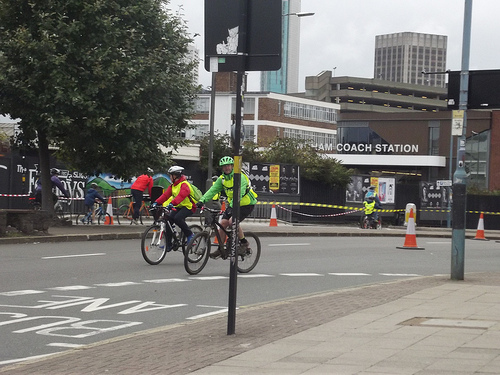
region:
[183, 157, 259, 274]
a man in a green jacket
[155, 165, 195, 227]
a person in a red jacket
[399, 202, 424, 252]
an orange cone in the street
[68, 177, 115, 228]
a little boy on a bike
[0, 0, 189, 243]
a tree in grass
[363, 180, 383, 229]
father and son riding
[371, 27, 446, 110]
a tall office building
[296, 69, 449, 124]
a very large parking garage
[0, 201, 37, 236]
a bench in the park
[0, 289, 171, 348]
white bus lane lettering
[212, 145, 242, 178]
head of a person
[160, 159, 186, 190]
head of a person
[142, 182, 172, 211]
arm of a person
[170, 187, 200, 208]
arm of a person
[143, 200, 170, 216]
hand of a person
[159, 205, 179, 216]
hand of a person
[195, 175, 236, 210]
arm of a person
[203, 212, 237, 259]
leg of a person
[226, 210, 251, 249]
leg of a person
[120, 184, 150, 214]
leg of a person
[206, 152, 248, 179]
head of a person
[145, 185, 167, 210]
arm of a person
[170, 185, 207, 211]
arm of a person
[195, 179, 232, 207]
arm of a person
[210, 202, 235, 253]
leg of a person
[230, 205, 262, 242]
leg of a person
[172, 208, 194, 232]
leg of a person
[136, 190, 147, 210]
leg of a person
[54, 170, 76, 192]
arm of a person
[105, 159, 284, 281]
bikers on the road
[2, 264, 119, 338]
white paint on street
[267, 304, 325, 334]
bricks on the ground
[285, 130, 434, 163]
sign for train station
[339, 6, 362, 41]
the sky is cloudy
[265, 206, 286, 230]
cone on the road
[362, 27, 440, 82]
top of the building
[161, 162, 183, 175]
helmet on the head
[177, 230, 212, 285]
wheel of the bike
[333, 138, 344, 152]
The letter is white.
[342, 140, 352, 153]
The letter is white.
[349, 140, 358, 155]
The letter is white.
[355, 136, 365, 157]
The letter is white.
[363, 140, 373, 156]
The letter is white.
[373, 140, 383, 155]
The letter is white.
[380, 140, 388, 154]
The letter is white.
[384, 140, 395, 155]
The letter is white.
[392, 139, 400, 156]
The letter is white.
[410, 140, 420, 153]
The letter is white.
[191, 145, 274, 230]
person on bike with green helmet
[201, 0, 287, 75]
back of sign posted on city sidewalk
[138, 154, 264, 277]
bike riders dressed in reflective gear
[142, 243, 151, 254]
orange reflector on bike's front wheel